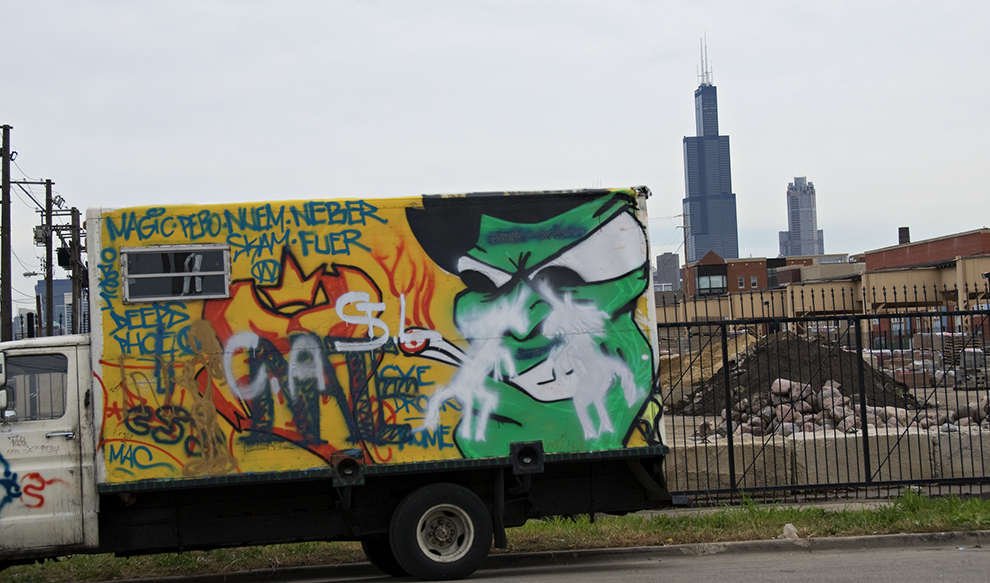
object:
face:
[404, 186, 652, 461]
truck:
[0, 184, 681, 582]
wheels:
[359, 484, 495, 583]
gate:
[720, 285, 990, 504]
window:
[0, 353, 69, 422]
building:
[682, 35, 738, 263]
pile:
[690, 379, 989, 436]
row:
[43, 179, 81, 336]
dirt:
[664, 330, 926, 417]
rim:
[417, 504, 478, 564]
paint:
[85, 188, 647, 485]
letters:
[97, 199, 386, 298]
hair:
[404, 189, 645, 275]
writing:
[17, 472, 47, 508]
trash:
[775, 522, 802, 542]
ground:
[116, 530, 990, 583]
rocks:
[688, 378, 990, 442]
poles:
[0, 124, 77, 340]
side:
[2, 0, 92, 548]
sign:
[84, 187, 667, 496]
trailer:
[88, 184, 676, 557]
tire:
[387, 481, 494, 582]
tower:
[682, 32, 738, 299]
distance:
[739, 190, 780, 258]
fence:
[663, 286, 990, 505]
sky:
[0, 0, 990, 338]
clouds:
[0, 2, 990, 319]